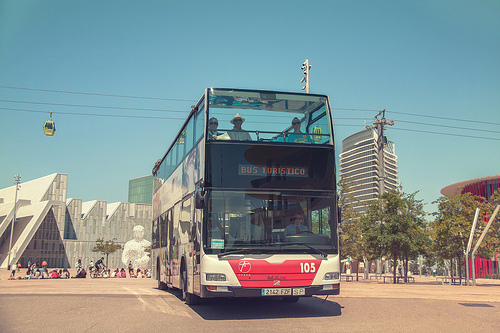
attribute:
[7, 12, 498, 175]
sky — blue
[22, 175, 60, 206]
wall — white